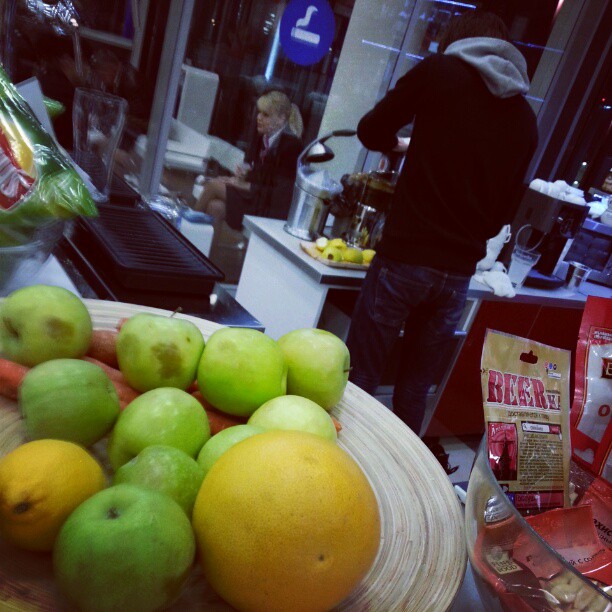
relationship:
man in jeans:
[365, 21, 540, 432] [347, 233, 482, 438]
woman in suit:
[231, 83, 302, 225] [230, 132, 297, 207]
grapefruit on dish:
[179, 423, 392, 609] [3, 285, 467, 611]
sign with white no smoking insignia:
[294, 65, 336, 78] [275, 131, 317, 142]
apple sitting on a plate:
[296, 334, 342, 398] [330, 451, 435, 612]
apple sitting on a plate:
[127, 403, 188, 456] [377, 436, 405, 477]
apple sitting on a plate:
[138, 444, 164, 541] [388, 550, 436, 612]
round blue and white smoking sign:
[241, 123, 262, 131] [290, 61, 320, 71]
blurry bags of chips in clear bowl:
[1, 117, 61, 256] [6, 170, 90, 267]